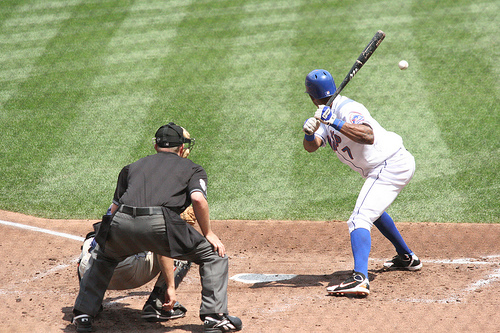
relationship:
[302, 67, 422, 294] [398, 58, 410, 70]
hitter about to hit a baseball